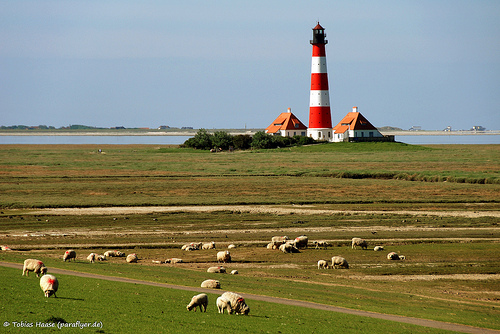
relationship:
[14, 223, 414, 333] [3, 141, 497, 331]
sheep in field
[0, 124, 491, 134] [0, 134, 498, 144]
sandbar across water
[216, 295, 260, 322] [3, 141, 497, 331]
sheep in field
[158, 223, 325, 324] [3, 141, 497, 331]
sheep in field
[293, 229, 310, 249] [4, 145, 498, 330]
sheep in grass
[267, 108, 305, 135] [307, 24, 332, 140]
house below lighthouse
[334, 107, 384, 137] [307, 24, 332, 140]
house below lighthouse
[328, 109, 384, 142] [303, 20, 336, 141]
house below lighthouse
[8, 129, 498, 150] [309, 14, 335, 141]
water behind lighthouse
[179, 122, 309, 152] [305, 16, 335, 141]
trees in front of lighthouse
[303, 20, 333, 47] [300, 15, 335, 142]
balcony on lighthouse